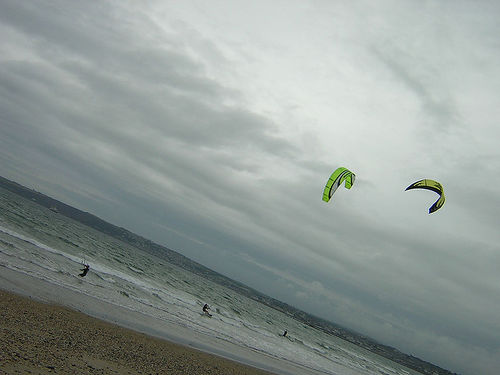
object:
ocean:
[2, 173, 499, 341]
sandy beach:
[2, 291, 493, 373]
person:
[74, 260, 98, 279]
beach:
[1, 276, 325, 374]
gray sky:
[1, 1, 499, 373]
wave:
[3, 217, 344, 373]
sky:
[2, 0, 499, 365]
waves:
[131, 240, 258, 342]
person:
[77, 260, 93, 282]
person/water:
[75, 260, 95, 280]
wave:
[225, 304, 242, 320]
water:
[49, 266, 182, 311]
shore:
[0, 291, 257, 373]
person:
[198, 297, 213, 319]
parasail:
[324, 163, 356, 196]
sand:
[14, 317, 181, 372]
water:
[1, 177, 421, 373]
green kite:
[315, 163, 362, 206]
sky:
[296, 107, 416, 186]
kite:
[318, 166, 360, 204]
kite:
[408, 176, 448, 216]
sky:
[126, 93, 240, 221]